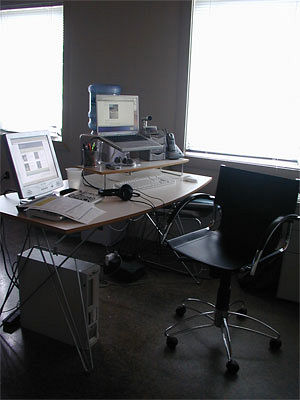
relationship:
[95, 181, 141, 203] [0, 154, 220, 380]
headphones on desk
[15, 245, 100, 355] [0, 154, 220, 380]
computer tower under desk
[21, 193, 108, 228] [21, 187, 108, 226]
papers on keyboard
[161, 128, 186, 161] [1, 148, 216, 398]
phone by computer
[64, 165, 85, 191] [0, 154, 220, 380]
cup on desk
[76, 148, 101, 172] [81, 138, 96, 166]
cup full of pens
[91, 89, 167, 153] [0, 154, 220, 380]
laptop on desk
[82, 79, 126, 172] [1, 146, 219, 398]
water dispenser behind desk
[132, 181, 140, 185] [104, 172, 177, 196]
key on keyboard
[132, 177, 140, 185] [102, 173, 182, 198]
key on keyboard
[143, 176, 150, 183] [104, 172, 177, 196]
key on keyboard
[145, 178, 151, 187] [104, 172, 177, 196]
key on keyboard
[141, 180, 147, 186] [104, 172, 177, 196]
key on keyboard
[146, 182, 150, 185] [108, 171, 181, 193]
key on keyboard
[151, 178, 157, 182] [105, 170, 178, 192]
key on keyboard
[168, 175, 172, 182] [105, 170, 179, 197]
key on keyboard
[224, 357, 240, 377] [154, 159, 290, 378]
wheel of chair